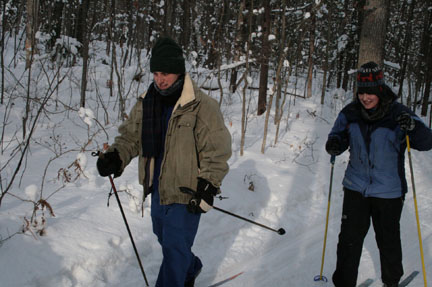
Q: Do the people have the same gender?
A: No, they are both male and female.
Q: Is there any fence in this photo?
A: No, there are no fences.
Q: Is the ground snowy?
A: Yes, the ground is snowy.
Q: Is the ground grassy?
A: No, the ground is snowy.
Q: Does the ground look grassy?
A: No, the ground is snowy.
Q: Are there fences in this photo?
A: No, there are no fences.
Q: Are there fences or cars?
A: No, there are no fences or cars.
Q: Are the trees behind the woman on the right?
A: Yes, the trees are behind the woman.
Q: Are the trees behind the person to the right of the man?
A: Yes, the trees are behind the woman.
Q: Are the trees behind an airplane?
A: No, the trees are behind the woman.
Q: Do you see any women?
A: Yes, there is a woman.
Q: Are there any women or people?
A: Yes, there is a woman.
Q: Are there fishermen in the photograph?
A: No, there are no fishermen.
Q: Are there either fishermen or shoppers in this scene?
A: No, there are no fishermen or shoppers.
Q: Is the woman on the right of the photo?
A: Yes, the woman is on the right of the image.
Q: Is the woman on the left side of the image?
A: No, the woman is on the right of the image.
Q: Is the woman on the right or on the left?
A: The woman is on the right of the image.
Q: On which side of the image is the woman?
A: The woman is on the right of the image.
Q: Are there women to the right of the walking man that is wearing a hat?
A: Yes, there is a woman to the right of the man.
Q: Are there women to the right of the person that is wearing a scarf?
A: Yes, there is a woman to the right of the man.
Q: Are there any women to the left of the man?
A: No, the woman is to the right of the man.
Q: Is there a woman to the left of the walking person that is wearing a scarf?
A: No, the woman is to the right of the man.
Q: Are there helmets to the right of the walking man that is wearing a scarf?
A: No, there is a woman to the right of the man.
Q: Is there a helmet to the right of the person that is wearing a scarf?
A: No, there is a woman to the right of the man.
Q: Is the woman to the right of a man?
A: Yes, the woman is to the right of a man.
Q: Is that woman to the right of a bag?
A: No, the woman is to the right of a man.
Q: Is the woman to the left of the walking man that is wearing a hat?
A: No, the woman is to the right of the man.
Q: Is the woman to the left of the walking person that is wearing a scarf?
A: No, the woman is to the right of the man.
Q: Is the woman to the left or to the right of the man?
A: The woman is to the right of the man.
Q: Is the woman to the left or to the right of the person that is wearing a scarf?
A: The woman is to the right of the man.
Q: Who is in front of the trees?
A: The woman is in front of the trees.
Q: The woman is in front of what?
A: The woman is in front of the trees.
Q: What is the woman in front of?
A: The woman is in front of the trees.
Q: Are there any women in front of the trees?
A: Yes, there is a woman in front of the trees.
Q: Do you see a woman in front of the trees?
A: Yes, there is a woman in front of the trees.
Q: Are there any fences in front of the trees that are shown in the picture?
A: No, there is a woman in front of the trees.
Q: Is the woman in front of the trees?
A: Yes, the woman is in front of the trees.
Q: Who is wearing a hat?
A: The woman is wearing a hat.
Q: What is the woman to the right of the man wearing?
A: The woman is wearing a hat.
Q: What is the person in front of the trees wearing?
A: The woman is wearing a hat.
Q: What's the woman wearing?
A: The woman is wearing a hat.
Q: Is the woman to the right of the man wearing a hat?
A: Yes, the woman is wearing a hat.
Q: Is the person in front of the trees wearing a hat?
A: Yes, the woman is wearing a hat.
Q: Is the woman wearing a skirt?
A: No, the woman is wearing a hat.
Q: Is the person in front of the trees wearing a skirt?
A: No, the woman is wearing a hat.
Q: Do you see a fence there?
A: No, there are no fences.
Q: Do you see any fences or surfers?
A: No, there are no fences or surfers.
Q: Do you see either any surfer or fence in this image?
A: No, there are no fences or surfers.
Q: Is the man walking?
A: Yes, the man is walking.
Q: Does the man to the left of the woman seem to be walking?
A: Yes, the man is walking.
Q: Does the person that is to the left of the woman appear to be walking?
A: Yes, the man is walking.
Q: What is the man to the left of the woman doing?
A: The man is walking.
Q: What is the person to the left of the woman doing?
A: The man is walking.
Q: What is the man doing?
A: The man is walking.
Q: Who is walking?
A: The man is walking.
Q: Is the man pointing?
A: No, the man is walking.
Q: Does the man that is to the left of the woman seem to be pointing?
A: No, the man is walking.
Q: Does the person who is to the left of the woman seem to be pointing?
A: No, the man is walking.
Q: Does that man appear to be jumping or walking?
A: The man is walking.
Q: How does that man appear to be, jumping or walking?
A: The man is walking.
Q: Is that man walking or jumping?
A: The man is walking.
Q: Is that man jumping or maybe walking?
A: The man is walking.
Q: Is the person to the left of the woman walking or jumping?
A: The man is walking.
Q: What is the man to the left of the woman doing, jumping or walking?
A: The man is walking.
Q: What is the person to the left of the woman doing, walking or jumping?
A: The man is walking.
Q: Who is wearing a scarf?
A: The man is wearing a scarf.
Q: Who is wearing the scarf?
A: The man is wearing a scarf.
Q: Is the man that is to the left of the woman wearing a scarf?
A: Yes, the man is wearing a scarf.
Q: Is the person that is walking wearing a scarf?
A: Yes, the man is wearing a scarf.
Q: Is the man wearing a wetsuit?
A: No, the man is wearing a scarf.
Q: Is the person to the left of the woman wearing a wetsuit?
A: No, the man is wearing a scarf.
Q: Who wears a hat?
A: The man wears a hat.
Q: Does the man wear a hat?
A: Yes, the man wears a hat.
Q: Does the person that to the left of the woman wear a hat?
A: Yes, the man wears a hat.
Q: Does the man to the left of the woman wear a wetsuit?
A: No, the man wears a hat.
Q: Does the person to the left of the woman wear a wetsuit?
A: No, the man wears a hat.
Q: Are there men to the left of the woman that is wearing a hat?
A: Yes, there is a man to the left of the woman.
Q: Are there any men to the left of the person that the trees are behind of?
A: Yes, there is a man to the left of the woman.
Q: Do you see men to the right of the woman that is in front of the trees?
A: No, the man is to the left of the woman.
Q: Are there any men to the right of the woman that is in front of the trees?
A: No, the man is to the left of the woman.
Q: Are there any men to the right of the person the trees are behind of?
A: No, the man is to the left of the woman.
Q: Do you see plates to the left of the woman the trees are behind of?
A: No, there is a man to the left of the woman.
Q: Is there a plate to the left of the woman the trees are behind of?
A: No, there is a man to the left of the woman.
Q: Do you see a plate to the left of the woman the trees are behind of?
A: No, there is a man to the left of the woman.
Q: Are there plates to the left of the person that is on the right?
A: No, there is a man to the left of the woman.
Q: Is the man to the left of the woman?
A: Yes, the man is to the left of the woman.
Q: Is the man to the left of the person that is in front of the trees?
A: Yes, the man is to the left of the woman.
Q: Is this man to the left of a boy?
A: No, the man is to the left of the woman.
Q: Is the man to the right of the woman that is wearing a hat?
A: No, the man is to the left of the woman.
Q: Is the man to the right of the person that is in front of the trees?
A: No, the man is to the left of the woman.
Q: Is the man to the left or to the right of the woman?
A: The man is to the left of the woman.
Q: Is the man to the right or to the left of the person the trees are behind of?
A: The man is to the left of the woman.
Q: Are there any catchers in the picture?
A: No, there are no catchers.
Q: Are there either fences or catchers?
A: No, there are no catchers or fences.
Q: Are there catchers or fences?
A: No, there are no catchers or fences.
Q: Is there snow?
A: Yes, there is snow.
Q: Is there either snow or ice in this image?
A: Yes, there is snow.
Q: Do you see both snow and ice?
A: No, there is snow but no ice.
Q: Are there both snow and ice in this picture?
A: No, there is snow but no ice.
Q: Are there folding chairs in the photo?
A: No, there are no folding chairs.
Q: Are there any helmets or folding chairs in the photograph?
A: No, there are no folding chairs or helmets.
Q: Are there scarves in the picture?
A: Yes, there is a scarf.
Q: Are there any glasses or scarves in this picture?
A: Yes, there is a scarf.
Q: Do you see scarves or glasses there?
A: Yes, there is a scarf.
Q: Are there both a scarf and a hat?
A: Yes, there are both a scarf and a hat.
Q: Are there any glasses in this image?
A: No, there are no glasses.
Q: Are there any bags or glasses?
A: No, there are no glasses or bags.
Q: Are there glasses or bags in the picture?
A: No, there are no glasses or bags.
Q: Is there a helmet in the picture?
A: No, there are no helmets.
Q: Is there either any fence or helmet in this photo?
A: No, there are no helmets or fences.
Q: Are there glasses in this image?
A: No, there are no glasses.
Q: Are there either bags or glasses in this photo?
A: No, there are no glasses or bags.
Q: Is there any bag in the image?
A: No, there are no bags.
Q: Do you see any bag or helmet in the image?
A: No, there are no bags or helmets.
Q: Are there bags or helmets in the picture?
A: No, there are no bags or helmets.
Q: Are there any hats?
A: Yes, there is a hat.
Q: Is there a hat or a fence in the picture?
A: Yes, there is a hat.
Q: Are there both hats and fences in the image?
A: No, there is a hat but no fences.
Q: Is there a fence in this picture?
A: No, there are no fences.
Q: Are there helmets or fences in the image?
A: No, there are no fences or helmets.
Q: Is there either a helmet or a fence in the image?
A: No, there are no fences or helmets.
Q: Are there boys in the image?
A: No, there are no boys.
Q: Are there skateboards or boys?
A: No, there are no boys or skateboards.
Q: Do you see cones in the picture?
A: No, there are no cones.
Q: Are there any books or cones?
A: No, there are no cones or books.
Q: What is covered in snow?
A: The branch is covered in snow.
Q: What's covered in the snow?
A: The branch is covered in snow.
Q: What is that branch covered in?
A: The branch is covered in snow.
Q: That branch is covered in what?
A: The branch is covered in snow.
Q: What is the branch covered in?
A: The branch is covered in snow.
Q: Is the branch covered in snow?
A: Yes, the branch is covered in snow.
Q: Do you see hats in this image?
A: Yes, there is a hat.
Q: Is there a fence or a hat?
A: Yes, there is a hat.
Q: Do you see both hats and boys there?
A: No, there is a hat but no boys.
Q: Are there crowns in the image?
A: No, there are no crowns.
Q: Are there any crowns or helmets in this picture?
A: No, there are no crowns or helmets.